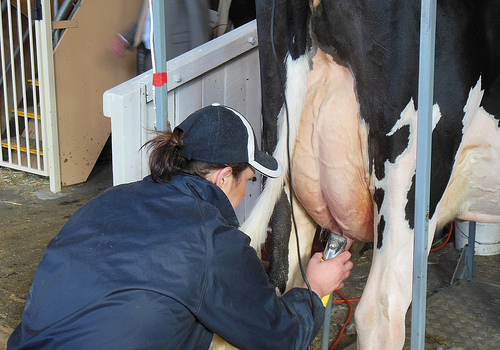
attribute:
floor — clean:
[14, 200, 41, 235]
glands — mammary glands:
[290, 103, 369, 221]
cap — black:
[177, 102, 294, 184]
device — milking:
[314, 228, 351, 307]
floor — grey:
[26, 131, 63, 258]